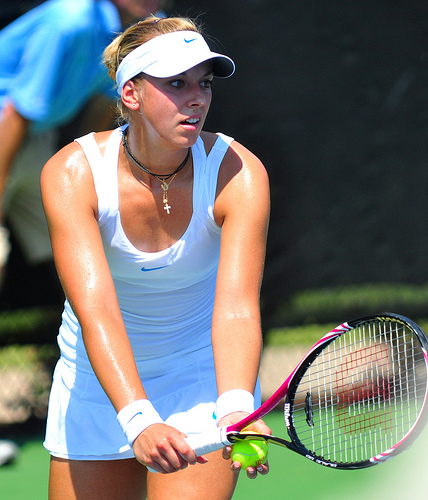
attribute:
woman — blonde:
[14, 5, 314, 497]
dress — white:
[41, 124, 265, 461]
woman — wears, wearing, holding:
[43, 12, 270, 498]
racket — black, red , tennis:
[170, 303, 426, 471]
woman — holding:
[34, 14, 293, 391]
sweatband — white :
[215, 385, 257, 414]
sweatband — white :
[116, 397, 158, 442]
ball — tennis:
[226, 429, 273, 464]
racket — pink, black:
[138, 305, 427, 477]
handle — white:
[169, 407, 248, 469]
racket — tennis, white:
[223, 333, 424, 470]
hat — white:
[114, 29, 235, 94]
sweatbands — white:
[116, 388, 255, 446]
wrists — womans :
[114, 390, 255, 437]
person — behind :
[0, 0, 168, 469]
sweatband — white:
[215, 387, 254, 420]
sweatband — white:
[117, 397, 164, 443]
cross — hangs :
[154, 199, 178, 215]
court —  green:
[13, 350, 412, 497]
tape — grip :
[164, 416, 237, 462]